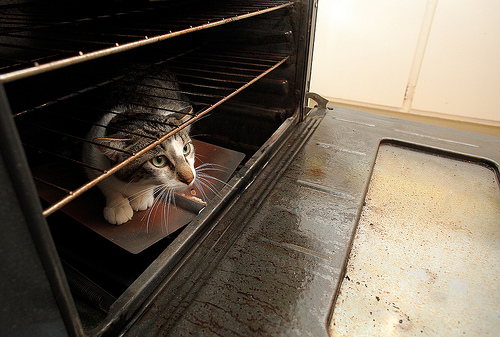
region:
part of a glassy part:
[431, 227, 465, 270]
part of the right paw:
[104, 210, 130, 223]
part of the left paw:
[132, 196, 151, 212]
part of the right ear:
[97, 134, 121, 159]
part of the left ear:
[174, 107, 192, 124]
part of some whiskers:
[203, 174, 239, 211]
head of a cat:
[138, 101, 160, 147]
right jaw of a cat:
[107, 152, 150, 194]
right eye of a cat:
[153, 152, 173, 167]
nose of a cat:
[178, 159, 195, 190]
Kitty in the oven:
[83, 102, 195, 229]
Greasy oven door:
[286, 158, 458, 326]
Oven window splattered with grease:
[373, 173, 475, 321]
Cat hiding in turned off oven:
[88, 71, 201, 226]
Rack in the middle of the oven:
[173, 48, 259, 86]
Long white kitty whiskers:
[125, 178, 190, 229]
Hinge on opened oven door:
[298, 79, 343, 131]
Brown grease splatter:
[298, 137, 339, 182]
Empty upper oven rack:
[13, 8, 154, 56]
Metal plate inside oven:
[114, 223, 171, 260]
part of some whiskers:
[203, 168, 219, 204]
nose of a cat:
[179, 170, 195, 182]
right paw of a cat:
[103, 207, 132, 230]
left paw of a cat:
[125, 198, 158, 214]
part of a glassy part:
[418, 215, 441, 252]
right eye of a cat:
[149, 154, 171, 176]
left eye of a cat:
[185, 145, 198, 155]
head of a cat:
[145, 115, 178, 156]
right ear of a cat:
[96, 134, 128, 161]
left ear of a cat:
[176, 89, 197, 133]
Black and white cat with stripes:
[52, 56, 209, 245]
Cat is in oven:
[76, 70, 264, 290]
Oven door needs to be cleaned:
[216, 141, 466, 325]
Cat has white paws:
[81, 136, 197, 263]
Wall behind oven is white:
[289, 5, 496, 192]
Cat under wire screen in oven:
[29, 47, 250, 254]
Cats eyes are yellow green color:
[106, 122, 213, 222]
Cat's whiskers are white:
[139, 122, 244, 255]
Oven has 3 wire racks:
[1, 6, 361, 282]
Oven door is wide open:
[219, 6, 483, 218]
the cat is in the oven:
[16, 0, 400, 327]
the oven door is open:
[19, 11, 495, 313]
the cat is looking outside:
[79, 74, 257, 315]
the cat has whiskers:
[123, 145, 255, 251]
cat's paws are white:
[88, 175, 206, 252]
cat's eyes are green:
[133, 127, 210, 173]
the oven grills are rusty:
[78, 29, 258, 304]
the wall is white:
[325, 6, 460, 128]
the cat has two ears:
[79, 105, 256, 179]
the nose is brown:
[159, 155, 214, 202]